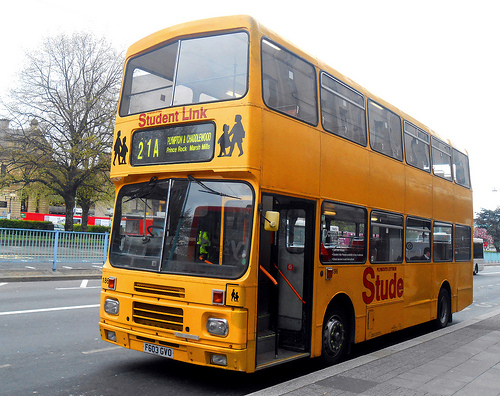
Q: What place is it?
A: It is a road.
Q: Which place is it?
A: It is a road.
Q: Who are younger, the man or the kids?
A: The kids are younger than the man.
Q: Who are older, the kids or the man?
A: The man are older than the kids.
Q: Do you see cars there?
A: No, there are no cars.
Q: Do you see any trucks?
A: No, there are no trucks.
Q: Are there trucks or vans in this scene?
A: No, there are no trucks or vans.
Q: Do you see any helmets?
A: No, there are no helmets.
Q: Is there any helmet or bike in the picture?
A: No, there are no helmets or bikes.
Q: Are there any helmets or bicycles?
A: No, there are no helmets or bicycles.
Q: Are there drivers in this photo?
A: No, there are no drivers.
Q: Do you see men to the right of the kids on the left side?
A: Yes, there is a man to the right of the kids.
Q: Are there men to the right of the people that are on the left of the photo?
A: Yes, there is a man to the right of the kids.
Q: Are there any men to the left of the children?
A: No, the man is to the right of the children.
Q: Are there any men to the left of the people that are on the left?
A: No, the man is to the right of the children.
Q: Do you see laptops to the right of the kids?
A: No, there is a man to the right of the kids.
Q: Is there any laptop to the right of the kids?
A: No, there is a man to the right of the kids.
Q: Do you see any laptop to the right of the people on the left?
A: No, there is a man to the right of the kids.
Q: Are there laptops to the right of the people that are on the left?
A: No, there is a man to the right of the kids.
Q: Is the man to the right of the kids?
A: Yes, the man is to the right of the kids.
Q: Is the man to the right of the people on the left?
A: Yes, the man is to the right of the kids.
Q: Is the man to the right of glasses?
A: No, the man is to the right of the kids.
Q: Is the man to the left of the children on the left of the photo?
A: No, the man is to the right of the kids.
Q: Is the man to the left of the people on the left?
A: No, the man is to the right of the kids.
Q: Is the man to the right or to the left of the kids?
A: The man is to the right of the kids.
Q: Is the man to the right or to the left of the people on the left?
A: The man is to the right of the kids.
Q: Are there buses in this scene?
A: Yes, there is a bus.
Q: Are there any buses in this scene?
A: Yes, there is a bus.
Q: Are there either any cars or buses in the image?
A: Yes, there is a bus.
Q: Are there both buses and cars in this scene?
A: No, there is a bus but no cars.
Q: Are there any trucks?
A: No, there are no trucks.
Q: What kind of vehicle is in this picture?
A: The vehicle is a bus.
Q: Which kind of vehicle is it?
A: The vehicle is a bus.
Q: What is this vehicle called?
A: This is a bus.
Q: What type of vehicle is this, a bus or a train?
A: This is a bus.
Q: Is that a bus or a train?
A: That is a bus.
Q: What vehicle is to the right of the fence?
A: The vehicle is a bus.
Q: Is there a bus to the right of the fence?
A: Yes, there is a bus to the right of the fence.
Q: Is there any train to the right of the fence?
A: No, there is a bus to the right of the fence.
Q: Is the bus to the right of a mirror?
A: No, the bus is to the right of a fence.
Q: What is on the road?
A: The bus is on the road.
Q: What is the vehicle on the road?
A: The vehicle is a bus.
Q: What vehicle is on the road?
A: The vehicle is a bus.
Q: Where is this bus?
A: The bus is on the road.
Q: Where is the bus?
A: The bus is on the road.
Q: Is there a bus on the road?
A: Yes, there is a bus on the road.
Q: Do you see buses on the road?
A: Yes, there is a bus on the road.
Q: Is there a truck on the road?
A: No, there is a bus on the road.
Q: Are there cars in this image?
A: No, there are no cars.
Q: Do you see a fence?
A: Yes, there is a fence.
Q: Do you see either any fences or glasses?
A: Yes, there is a fence.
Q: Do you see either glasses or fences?
A: Yes, there is a fence.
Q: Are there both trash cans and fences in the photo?
A: No, there is a fence but no trash cans.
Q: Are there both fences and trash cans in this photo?
A: No, there is a fence but no trash cans.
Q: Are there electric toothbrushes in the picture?
A: No, there are no electric toothbrushes.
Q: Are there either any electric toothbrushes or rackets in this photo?
A: No, there are no electric toothbrushes or rackets.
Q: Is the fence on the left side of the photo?
A: Yes, the fence is on the left of the image.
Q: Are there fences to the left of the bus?
A: Yes, there is a fence to the left of the bus.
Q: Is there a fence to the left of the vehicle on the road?
A: Yes, there is a fence to the left of the bus.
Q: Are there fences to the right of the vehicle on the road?
A: No, the fence is to the left of the bus.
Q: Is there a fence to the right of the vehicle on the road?
A: No, the fence is to the left of the bus.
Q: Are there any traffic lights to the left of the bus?
A: No, there is a fence to the left of the bus.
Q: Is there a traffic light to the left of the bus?
A: No, there is a fence to the left of the bus.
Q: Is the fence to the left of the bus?
A: Yes, the fence is to the left of the bus.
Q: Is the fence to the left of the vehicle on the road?
A: Yes, the fence is to the left of the bus.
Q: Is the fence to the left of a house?
A: No, the fence is to the left of the bus.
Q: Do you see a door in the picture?
A: Yes, there is a door.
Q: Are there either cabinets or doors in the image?
A: Yes, there is a door.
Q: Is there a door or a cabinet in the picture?
A: Yes, there is a door.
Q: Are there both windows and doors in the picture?
A: Yes, there are both a door and a window.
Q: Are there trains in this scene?
A: No, there are no trains.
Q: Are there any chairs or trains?
A: No, there are no trains or chairs.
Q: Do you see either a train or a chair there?
A: No, there are no trains or chairs.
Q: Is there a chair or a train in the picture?
A: No, there are no trains or chairs.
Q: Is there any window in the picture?
A: Yes, there are windows.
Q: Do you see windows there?
A: Yes, there are windows.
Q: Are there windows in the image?
A: Yes, there are windows.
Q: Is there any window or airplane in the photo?
A: Yes, there are windows.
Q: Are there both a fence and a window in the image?
A: Yes, there are both a window and a fence.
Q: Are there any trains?
A: No, there are no trains.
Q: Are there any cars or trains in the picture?
A: No, there are no trains or cars.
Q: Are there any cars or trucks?
A: No, there are no cars or trucks.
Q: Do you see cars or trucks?
A: No, there are no cars or trucks.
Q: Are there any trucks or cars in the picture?
A: No, there are no cars or trucks.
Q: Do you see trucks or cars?
A: No, there are no cars or trucks.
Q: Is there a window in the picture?
A: Yes, there is a window.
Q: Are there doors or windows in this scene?
A: Yes, there is a window.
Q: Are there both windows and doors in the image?
A: Yes, there are both a window and a door.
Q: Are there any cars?
A: No, there are no cars.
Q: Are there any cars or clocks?
A: No, there are no cars or clocks.